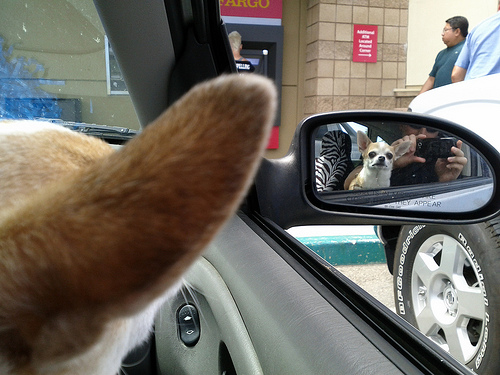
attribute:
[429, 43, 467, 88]
shirt — blue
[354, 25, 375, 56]
lettering — white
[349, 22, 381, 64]
sign — red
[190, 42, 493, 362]
window — down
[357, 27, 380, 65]
sign — red